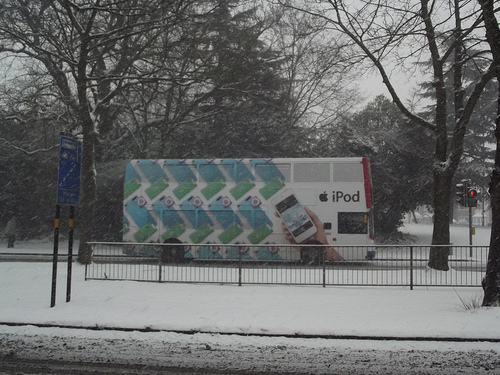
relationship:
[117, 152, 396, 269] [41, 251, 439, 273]
bus on road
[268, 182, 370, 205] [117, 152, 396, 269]
advertisement on bus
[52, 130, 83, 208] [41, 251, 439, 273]
sign beside road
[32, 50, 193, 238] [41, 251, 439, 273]
trees by road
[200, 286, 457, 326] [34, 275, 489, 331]
snow on ground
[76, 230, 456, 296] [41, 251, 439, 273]
fence by road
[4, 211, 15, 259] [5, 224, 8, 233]
man holding device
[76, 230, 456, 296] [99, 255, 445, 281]
fence by sidewalk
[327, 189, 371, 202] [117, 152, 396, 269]
ipod on bus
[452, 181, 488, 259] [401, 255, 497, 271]
traffic light on street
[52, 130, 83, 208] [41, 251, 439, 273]
sign on road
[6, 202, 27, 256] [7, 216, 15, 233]
person wearing jacket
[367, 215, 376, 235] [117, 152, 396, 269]
windshield on bus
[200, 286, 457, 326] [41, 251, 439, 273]
snow covered road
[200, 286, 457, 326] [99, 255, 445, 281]
snow covered sidewalk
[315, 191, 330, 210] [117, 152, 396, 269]
logo on bus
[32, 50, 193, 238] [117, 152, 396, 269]
trees near bus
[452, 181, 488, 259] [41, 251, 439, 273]
traffic light on road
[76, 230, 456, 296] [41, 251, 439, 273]
fence near road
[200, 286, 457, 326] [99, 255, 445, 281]
snow on sidewalk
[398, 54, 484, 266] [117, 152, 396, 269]
tree by bus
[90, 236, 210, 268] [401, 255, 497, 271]
gate near street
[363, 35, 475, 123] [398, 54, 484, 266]
branches on tree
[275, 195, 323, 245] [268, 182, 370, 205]
cellphon on advertisement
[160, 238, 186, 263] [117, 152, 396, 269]
wheel on bus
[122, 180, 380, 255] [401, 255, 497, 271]
vehicle on street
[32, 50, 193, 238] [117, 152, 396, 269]
trees behind bus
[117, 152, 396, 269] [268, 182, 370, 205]
bus has advertisement